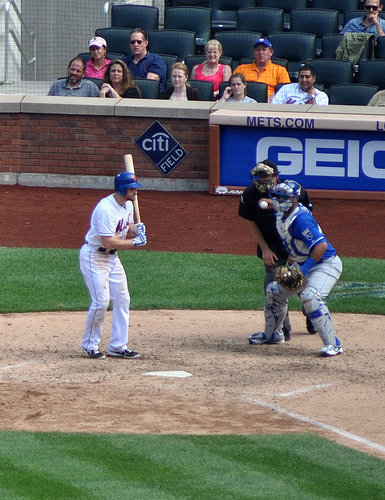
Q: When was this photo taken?
A: During daylight.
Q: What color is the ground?
A: Green and brown.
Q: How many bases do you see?
A: 1.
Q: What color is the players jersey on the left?
A: White.